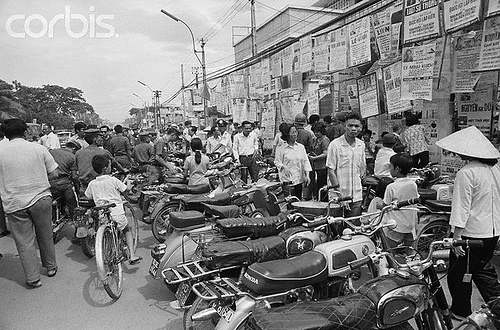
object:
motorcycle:
[170, 184, 341, 269]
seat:
[244, 292, 377, 330]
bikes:
[242, 237, 485, 329]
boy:
[376, 153, 421, 256]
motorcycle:
[160, 195, 353, 308]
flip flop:
[129, 256, 143, 265]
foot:
[130, 255, 140, 261]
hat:
[435, 125, 499, 161]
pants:
[4, 196, 57, 284]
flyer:
[399, 43, 436, 101]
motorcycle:
[190, 197, 423, 327]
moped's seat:
[242, 251, 329, 293]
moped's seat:
[201, 236, 287, 267]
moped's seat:
[215, 215, 285, 239]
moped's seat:
[200, 202, 242, 221]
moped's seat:
[160, 183, 211, 193]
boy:
[44, 141, 79, 223]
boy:
[84, 154, 144, 263]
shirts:
[273, 142, 312, 186]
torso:
[326, 138, 371, 208]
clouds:
[91, 55, 156, 67]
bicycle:
[93, 178, 139, 299]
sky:
[2, 1, 176, 88]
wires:
[154, 0, 259, 97]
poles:
[200, 49, 208, 126]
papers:
[310, 15, 377, 75]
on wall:
[301, 22, 413, 97]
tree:
[11, 79, 94, 130]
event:
[401, 51, 429, 80]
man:
[446, 150, 500, 329]